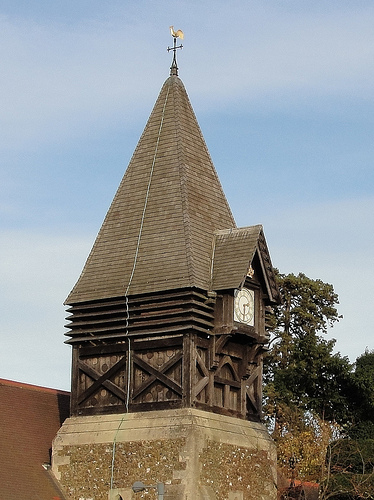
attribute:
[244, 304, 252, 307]
dials — metal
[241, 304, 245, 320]
dials — metal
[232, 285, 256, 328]
clock — square, white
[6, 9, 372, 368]
sky — clear, light blue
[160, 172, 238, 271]
roof — red, bricked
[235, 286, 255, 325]
clockface — white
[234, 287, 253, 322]
clock — white, square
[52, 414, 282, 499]
base — brick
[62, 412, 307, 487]
base — concrete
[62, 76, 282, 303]
roof — bricked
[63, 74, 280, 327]
roof — tiled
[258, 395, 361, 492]
leaves — yellow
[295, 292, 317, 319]
tree — green